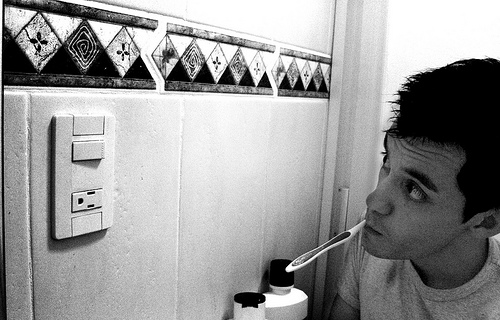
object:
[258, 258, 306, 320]
mouthwash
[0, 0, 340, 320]
wall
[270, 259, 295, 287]
black lid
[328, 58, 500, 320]
boy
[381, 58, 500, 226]
hair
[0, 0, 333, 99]
border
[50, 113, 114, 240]
outlet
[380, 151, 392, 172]
eye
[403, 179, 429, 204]
eye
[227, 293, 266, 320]
bottle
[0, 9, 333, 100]
row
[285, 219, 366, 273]
fire hydrant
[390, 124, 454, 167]
wrinkles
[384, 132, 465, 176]
forehead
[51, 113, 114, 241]
light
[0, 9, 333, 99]
patterns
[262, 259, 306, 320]
bottle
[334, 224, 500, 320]
shirt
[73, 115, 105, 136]
switch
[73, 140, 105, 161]
switch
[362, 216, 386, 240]
mouth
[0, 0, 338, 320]
tiles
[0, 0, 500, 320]
bathroom